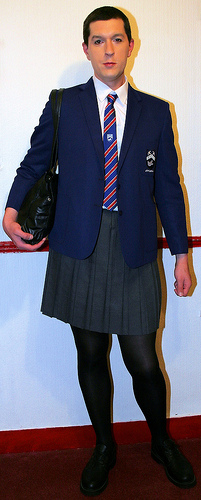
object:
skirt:
[37, 200, 160, 337]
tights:
[69, 318, 168, 449]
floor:
[0, 438, 201, 496]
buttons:
[118, 204, 123, 216]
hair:
[83, 6, 133, 50]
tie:
[102, 91, 119, 218]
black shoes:
[78, 422, 117, 495]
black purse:
[11, 86, 62, 245]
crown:
[1, 234, 46, 256]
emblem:
[146, 148, 155, 167]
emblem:
[106, 130, 113, 142]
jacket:
[4, 77, 189, 268]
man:
[2, 5, 197, 498]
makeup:
[86, 18, 127, 81]